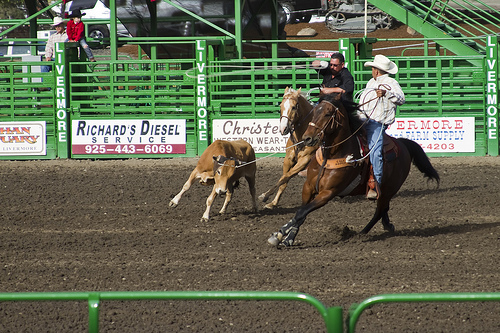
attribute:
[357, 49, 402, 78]
hat — white, cowboy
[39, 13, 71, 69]
person — sitting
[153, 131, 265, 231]
cow — small , brown  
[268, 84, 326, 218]
horse — brown  , lighter 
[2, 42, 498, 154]
fencing — green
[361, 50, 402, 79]
cowboy hat — white 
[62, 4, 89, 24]
cowboy hat — Black 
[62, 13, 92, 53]
shirt — red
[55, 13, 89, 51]
shirt — red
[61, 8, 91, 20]
hat — black 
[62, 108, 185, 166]
sign — Rectangle 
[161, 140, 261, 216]
cow — small 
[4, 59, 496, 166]
railing — green , bright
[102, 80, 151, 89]
railing — bright green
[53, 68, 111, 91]
railing — bright green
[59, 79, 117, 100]
railing — bright green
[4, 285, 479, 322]
railing — bright green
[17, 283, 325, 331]
railing — bright green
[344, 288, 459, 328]
railing — bright green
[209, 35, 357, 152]
railing — bright green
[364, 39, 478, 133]
railing — bright green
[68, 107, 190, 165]
sign — for Richards Diesel Service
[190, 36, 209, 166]
pole — green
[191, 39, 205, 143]
letters — white, saying Livermore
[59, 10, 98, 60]
cowboy — young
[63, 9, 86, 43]
shirt — red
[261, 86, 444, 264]
horse — dark brown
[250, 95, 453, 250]
horse — dark colored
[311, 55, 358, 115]
shirt — black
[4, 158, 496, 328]
dirt — Brown 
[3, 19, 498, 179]
metal fence — green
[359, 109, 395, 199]
jeans — blue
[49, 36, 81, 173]
post — green, says Livermore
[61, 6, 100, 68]
boy — young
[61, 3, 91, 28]
cowboy hat — black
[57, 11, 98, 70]
boy — young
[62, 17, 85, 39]
shirt — red